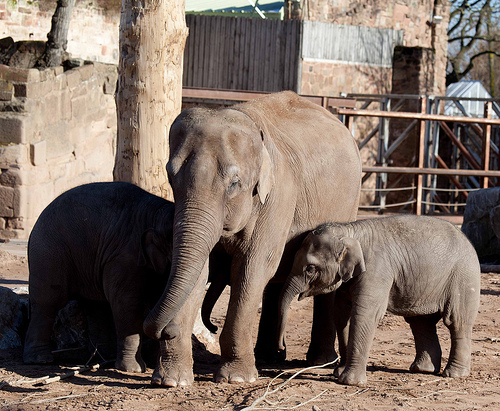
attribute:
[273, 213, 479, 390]
elephant — smallest, baby, gray, standing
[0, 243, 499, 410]
ground — dirt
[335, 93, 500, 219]
fencing — metal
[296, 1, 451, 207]
wall — brick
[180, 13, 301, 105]
fence — wooden, wood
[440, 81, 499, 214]
building — silver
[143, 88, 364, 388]
elephant — large, adult, bigger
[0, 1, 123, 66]
wall — stone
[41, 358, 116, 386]
branch — gray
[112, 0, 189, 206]
tree — gray, large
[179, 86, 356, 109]
bars — brown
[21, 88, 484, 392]
elephants — standing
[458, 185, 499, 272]
rock — grey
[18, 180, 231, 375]
elephant — smaller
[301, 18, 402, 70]
cover — silver